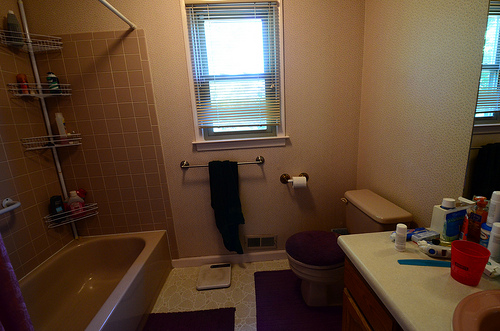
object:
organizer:
[0, 0, 105, 239]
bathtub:
[17, 230, 172, 331]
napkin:
[292, 177, 307, 189]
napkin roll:
[291, 177, 307, 189]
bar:
[181, 161, 262, 168]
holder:
[280, 172, 309, 183]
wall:
[389, 0, 468, 120]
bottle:
[394, 224, 408, 252]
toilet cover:
[285, 231, 345, 267]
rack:
[0, 30, 98, 229]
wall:
[1, 165, 42, 218]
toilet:
[285, 189, 414, 307]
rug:
[253, 269, 343, 331]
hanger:
[180, 156, 265, 170]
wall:
[100, 64, 145, 213]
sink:
[452, 289, 500, 330]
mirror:
[462, 0, 500, 202]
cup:
[450, 240, 491, 287]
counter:
[337, 227, 499, 331]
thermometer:
[379, 210, 451, 267]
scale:
[196, 263, 231, 291]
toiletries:
[389, 191, 500, 287]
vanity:
[336, 227, 498, 329]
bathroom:
[0, 0, 500, 331]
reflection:
[488, 48, 497, 129]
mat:
[142, 307, 236, 331]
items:
[389, 189, 498, 287]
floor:
[150, 258, 291, 331]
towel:
[208, 160, 245, 254]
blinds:
[180, 0, 286, 140]